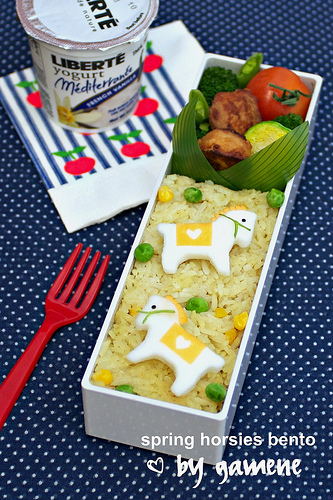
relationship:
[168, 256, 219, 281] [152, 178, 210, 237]
rice with corn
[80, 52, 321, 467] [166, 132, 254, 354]
box of food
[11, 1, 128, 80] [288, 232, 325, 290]
yogurt on table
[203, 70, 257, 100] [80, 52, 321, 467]
broccoli on box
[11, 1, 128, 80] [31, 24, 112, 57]
yogurt on top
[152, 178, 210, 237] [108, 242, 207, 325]
corn and peas